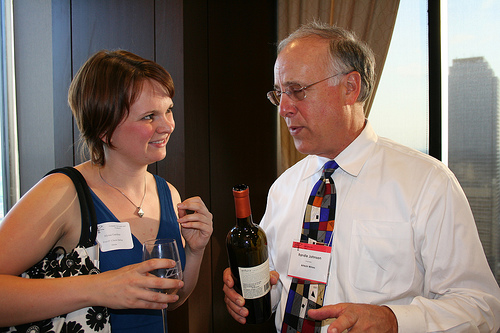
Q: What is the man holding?
A: Wine bottle.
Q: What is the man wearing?
A: Glasses.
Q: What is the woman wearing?
A: Dress.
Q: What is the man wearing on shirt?
A: Tie.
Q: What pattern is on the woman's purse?
A: Floral.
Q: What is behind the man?
A: Window.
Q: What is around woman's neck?
A: Necklace.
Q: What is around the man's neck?
A: A tie.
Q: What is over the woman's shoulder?
A: A black and white purse.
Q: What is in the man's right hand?
A: Wine.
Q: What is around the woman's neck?
A: A necklace.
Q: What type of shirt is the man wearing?
A: A white dress shirt.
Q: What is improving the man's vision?
A: Glasses.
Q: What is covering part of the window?
A: Curtains.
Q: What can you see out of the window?
A: A building.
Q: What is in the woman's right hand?
A: A wine glass.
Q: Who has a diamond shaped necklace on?
A: Woman on left.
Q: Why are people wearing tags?
A: Share names.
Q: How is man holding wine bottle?
A: Right hand.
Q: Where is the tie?
A: Man's neck.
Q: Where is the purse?
A: Woman's right shoulder.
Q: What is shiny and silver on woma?
A: Necklace.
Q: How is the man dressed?
A: Shirt and tie.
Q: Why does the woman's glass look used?
A: Had wine.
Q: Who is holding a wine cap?
A: The woman.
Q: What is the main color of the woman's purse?
A: White and black.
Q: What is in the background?
A: Skyscraper.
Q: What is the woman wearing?
A: A necklace.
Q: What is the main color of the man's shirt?
A: White.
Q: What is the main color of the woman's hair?
A: Red.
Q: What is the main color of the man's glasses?
A: Black.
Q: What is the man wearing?
A: Glasses.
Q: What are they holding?
A: Wine.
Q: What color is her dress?
A: Blue.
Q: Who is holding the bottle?
A: The man.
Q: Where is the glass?
A: In the woman's hands.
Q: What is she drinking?
A: Wine.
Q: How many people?
A: 2.